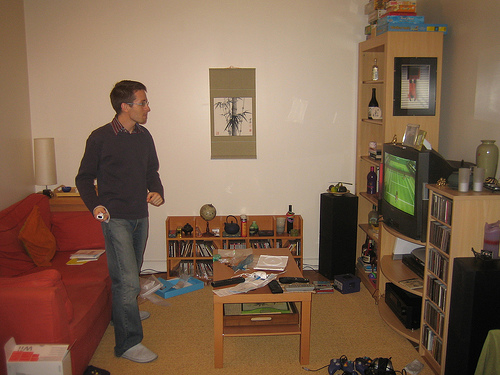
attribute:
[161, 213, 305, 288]
organizer — blonde, wood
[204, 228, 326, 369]
table — small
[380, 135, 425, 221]
tv screen — on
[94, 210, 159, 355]
jeans — blue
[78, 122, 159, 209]
sweater — dark grey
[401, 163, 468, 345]
wood — blonde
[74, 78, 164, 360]
man — dark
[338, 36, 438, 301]
bookcase — wood, blonde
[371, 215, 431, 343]
tv stand — blonde, wood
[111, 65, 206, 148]
head — man's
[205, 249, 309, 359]
table — wood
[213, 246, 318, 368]
coffee table — blonde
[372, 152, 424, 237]
tv set — black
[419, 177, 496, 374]
organizer — media organizer, wood, blonde wood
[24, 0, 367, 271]
wall — white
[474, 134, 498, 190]
vase — green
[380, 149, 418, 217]
screen — on